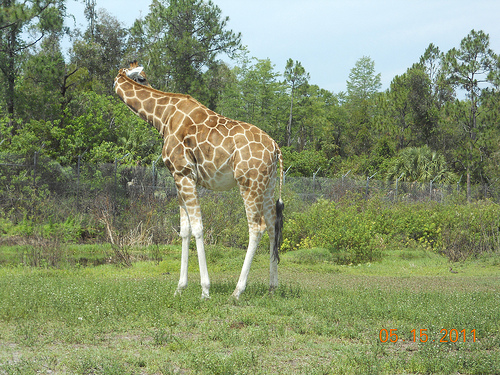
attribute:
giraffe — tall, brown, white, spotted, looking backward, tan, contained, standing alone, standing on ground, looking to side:
[111, 59, 286, 302]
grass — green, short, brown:
[1, 233, 499, 374]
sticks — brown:
[94, 199, 126, 261]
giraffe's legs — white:
[178, 214, 259, 296]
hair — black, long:
[272, 199, 284, 265]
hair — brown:
[118, 59, 190, 101]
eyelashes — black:
[135, 76, 150, 85]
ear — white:
[126, 64, 146, 81]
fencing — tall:
[2, 149, 496, 203]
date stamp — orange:
[375, 324, 479, 351]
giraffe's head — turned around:
[121, 58, 155, 90]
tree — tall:
[443, 30, 499, 203]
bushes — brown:
[22, 190, 181, 267]